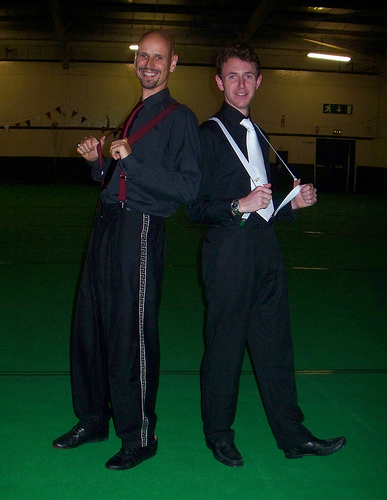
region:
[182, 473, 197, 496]
THE FLOOR IS GREEN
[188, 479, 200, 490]
THE FLOOR IS GREEN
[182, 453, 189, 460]
THE FLOOR IS GREEN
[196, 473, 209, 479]
THE FLOOR IS GREEN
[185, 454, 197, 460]
THE FLOOR IS GREEN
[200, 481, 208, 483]
THE FLOOR IS GREEN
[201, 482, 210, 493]
THE FLOOR IS GREEN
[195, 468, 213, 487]
THE FLOOR IS GREEN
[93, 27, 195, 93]
man with bald head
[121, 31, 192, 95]
man with two ears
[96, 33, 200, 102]
man with big smile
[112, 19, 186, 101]
man with facial hair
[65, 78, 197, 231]
man wearing dress black shirt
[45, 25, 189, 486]
man wearing dress black pants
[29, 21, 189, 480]
man wearing a pair of black shoes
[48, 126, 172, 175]
man wearing a ring on his right hand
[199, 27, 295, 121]
man with short brown hair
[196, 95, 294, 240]
man wearing dress white tie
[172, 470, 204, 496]
The floor is green.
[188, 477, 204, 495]
The floor is green.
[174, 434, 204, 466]
The floor is green.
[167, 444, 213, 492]
The floor is green.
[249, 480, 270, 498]
The floor is green.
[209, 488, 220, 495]
The floor is green.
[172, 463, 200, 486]
The floor is green.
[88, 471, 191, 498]
large green flooring on the ground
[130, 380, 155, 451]
black and white stripe on side of pants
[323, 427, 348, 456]
heel of black shoes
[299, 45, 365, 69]
white line in the ceiling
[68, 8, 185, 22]
wood beams in the ceiling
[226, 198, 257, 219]
black face of silver watch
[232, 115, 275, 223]
elegant white tie around man's neck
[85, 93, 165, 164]
red suspenders on man's shirt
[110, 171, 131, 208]
buckles on red suspenders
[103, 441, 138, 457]
black laces in shoes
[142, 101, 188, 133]
Maroon suspenders on a man's shirt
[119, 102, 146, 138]
Maroon tie on a man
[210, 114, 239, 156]
White suspenders on a man's shoulder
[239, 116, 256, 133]
Knot in a man's white tie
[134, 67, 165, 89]
Mustache and beard on a man's face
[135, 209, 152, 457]
White stripe on a man's pants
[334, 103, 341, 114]
Arrow pointing down on a sign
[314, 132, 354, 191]
Door on the back of a room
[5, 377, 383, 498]
Green floor under man's feet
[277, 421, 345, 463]
Man's black shoe kicked up